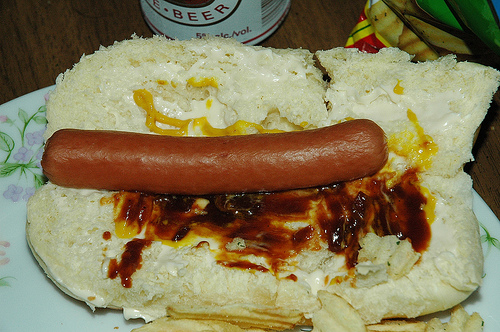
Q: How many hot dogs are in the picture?
A: One.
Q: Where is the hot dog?
A: On the bun.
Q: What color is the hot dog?
A: Pink.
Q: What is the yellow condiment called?
A: Mustard.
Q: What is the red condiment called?
A: Ketchup.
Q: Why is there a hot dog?
A: To eat.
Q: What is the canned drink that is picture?
A: A beer.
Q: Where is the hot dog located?
A: On a piece of bread.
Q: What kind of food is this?
A: Hot dog.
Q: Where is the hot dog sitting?
A: Inside bun.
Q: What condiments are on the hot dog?
A: Barbecue sauce and mustard.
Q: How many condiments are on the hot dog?
A: Two.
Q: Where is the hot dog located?
A: Plate.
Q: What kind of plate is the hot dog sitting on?
A: Paper plate.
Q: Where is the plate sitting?
A: Table.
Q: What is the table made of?
A: Wood.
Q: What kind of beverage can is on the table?
A: Beer.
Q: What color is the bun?
A: White.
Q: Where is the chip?
A: On bun.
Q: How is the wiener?
A: Cooked.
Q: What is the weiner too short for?
A: Bun.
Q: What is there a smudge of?
A: Mustard.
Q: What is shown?
A: Sauce.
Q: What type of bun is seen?
A: High carb.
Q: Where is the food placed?
A: On a plate.